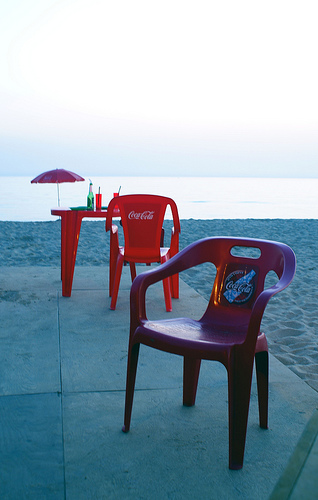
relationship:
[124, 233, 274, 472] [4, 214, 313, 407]
chair at beach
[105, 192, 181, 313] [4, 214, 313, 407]
chair at beach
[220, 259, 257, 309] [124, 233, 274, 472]
coca cola logo on front of chair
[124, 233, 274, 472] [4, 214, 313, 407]
chair on beach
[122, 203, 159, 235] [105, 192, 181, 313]
coca cola logo on back of chair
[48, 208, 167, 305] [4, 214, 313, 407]
table on beach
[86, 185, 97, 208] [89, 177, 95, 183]
bottle with straw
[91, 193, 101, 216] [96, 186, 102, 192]
tumbler with straw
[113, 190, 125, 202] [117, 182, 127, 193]
tumbler with straw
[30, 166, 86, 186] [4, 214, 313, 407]
umbrella on beach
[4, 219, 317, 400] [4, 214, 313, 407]
sand on beach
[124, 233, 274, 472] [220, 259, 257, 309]
chair with coca cola logo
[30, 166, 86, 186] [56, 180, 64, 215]
umbrella on a rod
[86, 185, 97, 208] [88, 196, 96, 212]
bottle with label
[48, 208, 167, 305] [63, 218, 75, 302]
table has leg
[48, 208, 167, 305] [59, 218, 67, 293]
table has leg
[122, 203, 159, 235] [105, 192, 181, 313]
coca cola logo on chair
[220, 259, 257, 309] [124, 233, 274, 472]
coca cola logo on chair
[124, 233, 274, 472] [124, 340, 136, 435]
chair has leg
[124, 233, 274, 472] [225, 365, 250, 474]
chair has leg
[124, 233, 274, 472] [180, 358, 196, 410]
chair has leg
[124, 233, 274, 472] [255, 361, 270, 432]
chair has leg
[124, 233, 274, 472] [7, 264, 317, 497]
chair on floor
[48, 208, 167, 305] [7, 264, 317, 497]
table on floor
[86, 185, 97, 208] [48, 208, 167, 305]
bottle sitting on table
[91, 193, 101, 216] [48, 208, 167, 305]
tumbler sitting on table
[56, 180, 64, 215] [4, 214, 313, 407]
rod on beach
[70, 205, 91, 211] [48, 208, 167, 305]
plate on table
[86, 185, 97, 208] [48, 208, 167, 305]
bottle on table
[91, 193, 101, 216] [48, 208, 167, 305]
tumbler on table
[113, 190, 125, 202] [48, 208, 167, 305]
tumbler on table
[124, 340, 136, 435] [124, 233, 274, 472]
leg of chair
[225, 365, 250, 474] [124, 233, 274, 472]
leg of chair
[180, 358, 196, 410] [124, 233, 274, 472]
leg of chair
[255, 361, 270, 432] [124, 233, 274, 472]
leg of chair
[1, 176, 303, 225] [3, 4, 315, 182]
water meets sky